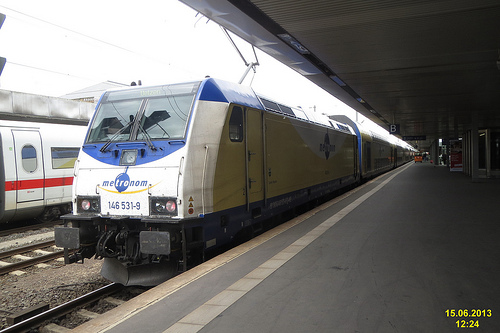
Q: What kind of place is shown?
A: It is a station.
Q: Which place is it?
A: It is a station.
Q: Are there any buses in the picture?
A: No, there are no buses.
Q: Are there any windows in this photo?
A: Yes, there is a window.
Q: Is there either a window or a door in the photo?
A: Yes, there is a window.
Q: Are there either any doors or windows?
A: Yes, there is a window.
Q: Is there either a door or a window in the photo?
A: Yes, there is a window.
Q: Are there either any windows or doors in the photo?
A: Yes, there is a window.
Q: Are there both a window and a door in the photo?
A: Yes, there are both a window and a door.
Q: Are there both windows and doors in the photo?
A: Yes, there are both a window and a door.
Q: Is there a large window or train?
A: Yes, there is a large window.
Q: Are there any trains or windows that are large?
A: Yes, the window is large.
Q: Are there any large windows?
A: Yes, there is a large window.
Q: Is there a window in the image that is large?
A: Yes, there is a window that is large.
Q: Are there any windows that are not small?
A: Yes, there is a large window.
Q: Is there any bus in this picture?
A: No, there are no buses.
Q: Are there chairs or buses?
A: No, there are no buses or chairs.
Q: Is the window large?
A: Yes, the window is large.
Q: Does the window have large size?
A: Yes, the window is large.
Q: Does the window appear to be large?
A: Yes, the window is large.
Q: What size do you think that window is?
A: The window is large.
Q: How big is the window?
A: The window is large.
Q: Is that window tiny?
A: No, the window is large.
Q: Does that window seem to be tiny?
A: No, the window is large.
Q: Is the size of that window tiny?
A: No, the window is large.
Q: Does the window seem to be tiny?
A: No, the window is large.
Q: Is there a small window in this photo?
A: No, there is a window but it is large.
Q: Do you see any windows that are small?
A: No, there is a window but it is large.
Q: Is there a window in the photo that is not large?
A: No, there is a window but it is large.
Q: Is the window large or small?
A: The window is large.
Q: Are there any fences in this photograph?
A: No, there are no fences.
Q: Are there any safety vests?
A: No, there are no safety vests.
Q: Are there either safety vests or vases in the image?
A: No, there are no safety vests or vases.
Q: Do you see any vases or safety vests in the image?
A: No, there are no safety vests or vases.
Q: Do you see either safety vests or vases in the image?
A: No, there are no safety vests or vases.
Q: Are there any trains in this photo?
A: Yes, there is a train.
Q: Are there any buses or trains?
A: Yes, there is a train.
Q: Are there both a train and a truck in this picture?
A: No, there is a train but no trucks.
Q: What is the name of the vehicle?
A: The vehicle is a train.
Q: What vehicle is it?
A: The vehicle is a train.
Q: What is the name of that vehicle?
A: This is a train.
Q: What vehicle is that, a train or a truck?
A: This is a train.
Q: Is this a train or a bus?
A: This is a train.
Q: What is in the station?
A: The train is in the station.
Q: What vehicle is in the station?
A: The vehicle is a train.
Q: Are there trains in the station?
A: Yes, there is a train in the station.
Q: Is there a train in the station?
A: Yes, there is a train in the station.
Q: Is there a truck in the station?
A: No, there is a train in the station.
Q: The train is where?
A: The train is at the station.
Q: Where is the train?
A: The train is at the station.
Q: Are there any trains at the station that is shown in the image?
A: Yes, there is a train at the station.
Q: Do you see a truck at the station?
A: No, there is a train at the station.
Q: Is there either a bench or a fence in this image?
A: No, there are no fences or benches.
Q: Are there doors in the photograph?
A: Yes, there is a door.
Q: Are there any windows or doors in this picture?
A: Yes, there is a door.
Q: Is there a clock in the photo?
A: No, there are no clocks.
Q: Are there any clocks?
A: No, there are no clocks.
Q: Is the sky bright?
A: Yes, the sky is bright.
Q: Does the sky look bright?
A: Yes, the sky is bright.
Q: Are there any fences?
A: No, there are no fences.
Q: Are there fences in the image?
A: No, there are no fences.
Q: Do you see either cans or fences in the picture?
A: No, there are no fences or cans.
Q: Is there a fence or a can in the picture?
A: No, there are no fences or cans.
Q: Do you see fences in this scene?
A: No, there are no fences.